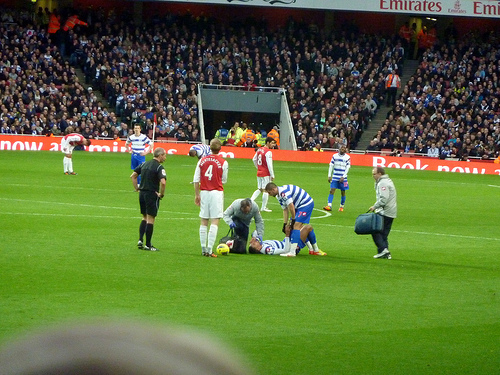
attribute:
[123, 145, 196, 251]
player — injured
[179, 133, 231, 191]
shirt — red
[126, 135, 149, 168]
uniform — blue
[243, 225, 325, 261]
player — wounded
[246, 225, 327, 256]
teammate — injured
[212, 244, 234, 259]
soccer ball — yellow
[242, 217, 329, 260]
player — injured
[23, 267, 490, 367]
grass — green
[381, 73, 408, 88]
vest — orange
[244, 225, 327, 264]
player — soccer, injured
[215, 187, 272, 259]
member — team